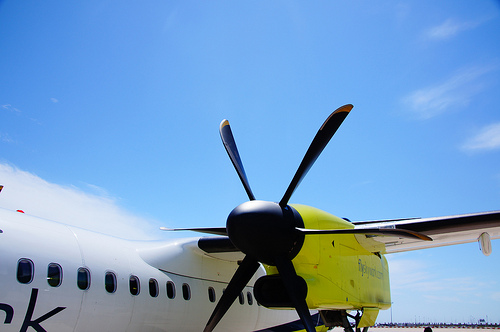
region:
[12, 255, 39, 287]
window one on plane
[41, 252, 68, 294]
window two on plane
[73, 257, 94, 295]
window three on plane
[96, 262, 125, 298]
fourth window on plane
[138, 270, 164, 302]
sixth window on plane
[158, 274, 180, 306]
seventh window on plane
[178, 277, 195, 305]
eigth window on plane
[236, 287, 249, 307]
tenth window on plane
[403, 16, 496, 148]
small clouds in the sky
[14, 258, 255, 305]
a row of windows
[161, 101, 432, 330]
the plane's propeller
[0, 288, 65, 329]
black lettering on the plane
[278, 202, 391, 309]
the engine is yellow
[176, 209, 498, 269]
the wing on the plane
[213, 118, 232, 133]
the tip is yellow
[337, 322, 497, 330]
the run way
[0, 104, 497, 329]
the side of a plane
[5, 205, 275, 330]
the plane is white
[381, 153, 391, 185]
There is a sky of blue here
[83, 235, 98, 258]
There is a white side of the plane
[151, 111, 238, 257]
Jackson Mingus took this photo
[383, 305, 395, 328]
There is a gray lamp post back there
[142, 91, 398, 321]
propelor on the plane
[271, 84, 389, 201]
blade of the propellor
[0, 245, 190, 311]
windows on the plane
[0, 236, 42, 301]
one window on plane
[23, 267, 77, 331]
letter on the plane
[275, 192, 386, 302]
yellow part of plane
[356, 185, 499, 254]
wing of the plane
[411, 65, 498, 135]
white clouds in the sky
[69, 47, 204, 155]
blue sky above land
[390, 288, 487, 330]
land and sky in distance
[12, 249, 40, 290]
Small window on a plane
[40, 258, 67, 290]
Small window on a plane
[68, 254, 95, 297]
Small window on a plane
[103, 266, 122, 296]
Small window on a plane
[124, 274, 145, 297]
Small window on a plane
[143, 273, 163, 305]
Small window on a plane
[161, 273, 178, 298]
Small window on a plane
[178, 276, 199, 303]
Small window on a plane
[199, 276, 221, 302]
Small window on a plane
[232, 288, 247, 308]
Small window on a plane